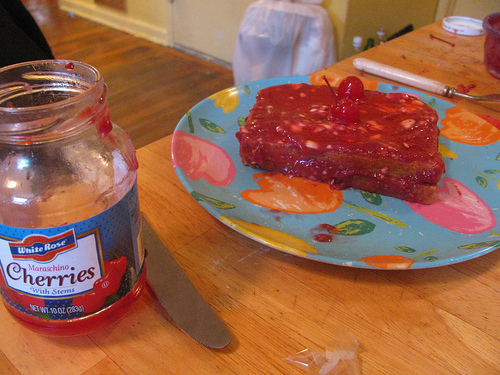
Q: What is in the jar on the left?
A: Cherries.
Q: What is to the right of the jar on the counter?
A: A knife.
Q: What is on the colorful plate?
A: Two slices of bread.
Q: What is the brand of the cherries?
A: White Rose.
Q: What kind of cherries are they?
A: Maraschino cherries.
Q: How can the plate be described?
A: A light blue background with orange and pink flowers.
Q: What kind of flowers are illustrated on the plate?
A: Tulips.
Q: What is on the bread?
A: Jam and cherries.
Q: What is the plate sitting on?
A: A wooden table.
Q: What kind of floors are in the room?
A: Hard wood floors.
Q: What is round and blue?
A: Plate.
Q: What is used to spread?
A: Knife.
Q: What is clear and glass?
A: Bottle.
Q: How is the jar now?
A: Empty.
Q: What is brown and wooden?
A: Table.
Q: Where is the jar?
A: To the left of the plate.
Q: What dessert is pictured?
A: Cherry.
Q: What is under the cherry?
A: Bread.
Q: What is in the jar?
A: Cherry jam.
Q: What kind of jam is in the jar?
A: Cherry.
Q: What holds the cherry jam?
A: Jar.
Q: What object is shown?
A: Jar of cherry jam.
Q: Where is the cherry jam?
A: In the jar.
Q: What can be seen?
A: Cherry jam jar.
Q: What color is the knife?
A: Silver.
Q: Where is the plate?
A: The table.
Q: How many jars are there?
A: One.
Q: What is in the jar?
A: Cherries.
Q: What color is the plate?
A: Blue.